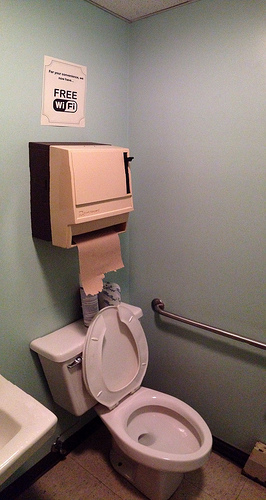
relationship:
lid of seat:
[83, 304, 150, 412] [80, 314, 156, 395]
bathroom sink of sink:
[0, 369, 58, 483] [0, 372, 61, 487]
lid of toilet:
[85, 300, 150, 407] [28, 294, 209, 492]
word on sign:
[49, 77, 92, 108] [23, 40, 135, 137]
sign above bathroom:
[23, 40, 135, 137] [0, 0, 266, 500]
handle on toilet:
[58, 353, 82, 372] [28, 294, 209, 492]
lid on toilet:
[83, 304, 150, 412] [28, 294, 209, 492]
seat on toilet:
[84, 304, 150, 409] [28, 294, 209, 492]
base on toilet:
[104, 437, 188, 497] [144, 473, 181, 495]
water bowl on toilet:
[28, 299, 144, 416] [3, 311, 218, 466]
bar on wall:
[150, 297, 265, 350] [164, 353, 222, 389]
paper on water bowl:
[77, 233, 125, 298] [18, 304, 157, 415]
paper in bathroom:
[77, 233, 125, 298] [3, 4, 264, 498]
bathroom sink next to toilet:
[0, 369, 58, 483] [28, 294, 209, 492]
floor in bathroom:
[32, 458, 115, 496] [3, 4, 264, 498]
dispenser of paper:
[27, 140, 133, 247] [75, 233, 125, 293]